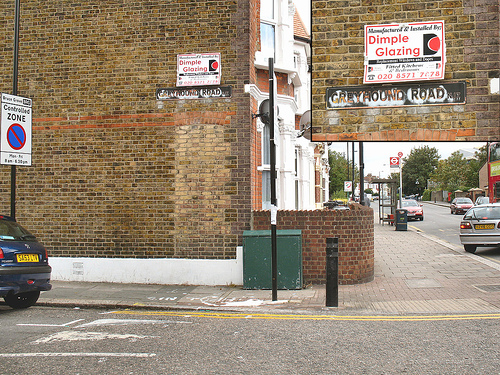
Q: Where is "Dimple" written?
A: On a sign.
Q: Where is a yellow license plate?
A: On blue car.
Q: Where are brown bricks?
A: On side of building.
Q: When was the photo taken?
A: During the daytime.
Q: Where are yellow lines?
A: On the road.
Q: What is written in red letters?
A: "Dimple Glazing".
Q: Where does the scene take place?
A: On a city street.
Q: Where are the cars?
A: On the street.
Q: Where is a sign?
A: On side of building.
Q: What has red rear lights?
A: Blue car.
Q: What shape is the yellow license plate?
A: Rectangular.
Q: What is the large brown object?
A: A brick wall.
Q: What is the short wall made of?
A: Brick.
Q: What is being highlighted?
A: A magnification of a business sign.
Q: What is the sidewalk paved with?
A: Brick.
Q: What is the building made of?
A: Brick.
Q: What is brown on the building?
A: Brick.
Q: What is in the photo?
A: Vehicles.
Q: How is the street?
A: Busy.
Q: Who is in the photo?
A: No one.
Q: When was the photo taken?
A: Daytime.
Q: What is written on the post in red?
A: Dimple Glazing.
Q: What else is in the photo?
A: A rubbish bin.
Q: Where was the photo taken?
A: On the street corner.